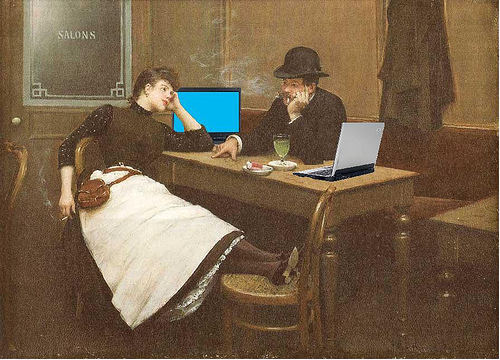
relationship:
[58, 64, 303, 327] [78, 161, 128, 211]
woman holding purse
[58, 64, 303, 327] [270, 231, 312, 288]
woman wearing heels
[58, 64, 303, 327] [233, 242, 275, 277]
woman wearing stockings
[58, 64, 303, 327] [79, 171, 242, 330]
woman wearing skirt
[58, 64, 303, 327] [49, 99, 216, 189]
woman wearing black shirt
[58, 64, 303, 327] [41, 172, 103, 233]
woman has hand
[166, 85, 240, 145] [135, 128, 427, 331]
laptops on table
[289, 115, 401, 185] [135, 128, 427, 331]
laptops on table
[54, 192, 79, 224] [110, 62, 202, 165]
hand of woman